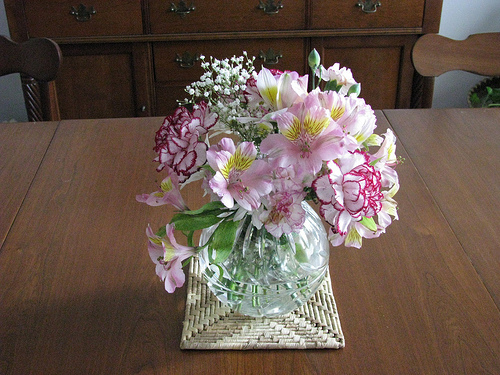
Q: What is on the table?
A: A vase of flowers.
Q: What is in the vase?
A: Purple and white flowers.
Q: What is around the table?
A: Two chairs and a cabinet.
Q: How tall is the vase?
A: Short.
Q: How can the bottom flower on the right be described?
A: A white flower with red tips.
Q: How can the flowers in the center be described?
A: Pink flowers with some yellow.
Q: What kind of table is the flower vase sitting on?
A: A wooden table.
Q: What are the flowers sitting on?
A: A coaster made from bamboo or banana leaves.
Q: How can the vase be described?
A: Round clear glass.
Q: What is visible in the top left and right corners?
A: Chairs.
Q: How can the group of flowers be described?
A: An assortment of flowers.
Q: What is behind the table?
A: Lower part of a wooden hutch.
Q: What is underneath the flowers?
A: Woven straw protective mat.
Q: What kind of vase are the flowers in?
A: Round crystal vase.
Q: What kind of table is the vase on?
A: Wooden.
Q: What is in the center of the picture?
A: A bouquet of flowers in a crystal vase.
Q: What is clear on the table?
A: The vase.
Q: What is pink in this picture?
A: The flowers.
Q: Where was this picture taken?
A: Dining room.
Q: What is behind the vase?
A: Wooden cabinet.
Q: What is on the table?
A: Flower.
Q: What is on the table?
A: Flowers.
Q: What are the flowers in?
A: Vase.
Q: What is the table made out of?
A: Wood.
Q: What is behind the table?
A: Drawers.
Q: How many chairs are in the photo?
A: Two.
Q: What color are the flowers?
A: Purple.